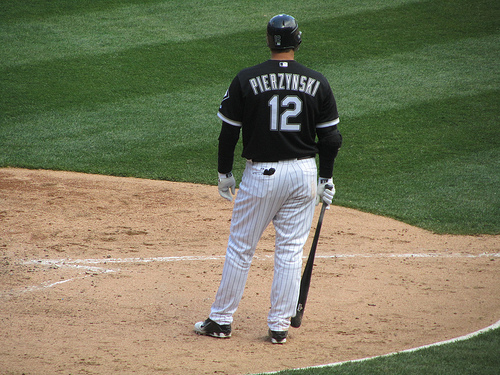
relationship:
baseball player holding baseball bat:
[189, 11, 346, 343] [273, 170, 335, 337]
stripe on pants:
[263, 182, 269, 216] [223, 158, 318, 326]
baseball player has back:
[189, 11, 346, 343] [239, 59, 326, 162]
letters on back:
[245, 67, 329, 97] [239, 59, 326, 162]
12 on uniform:
[267, 92, 304, 135] [209, 60, 342, 331]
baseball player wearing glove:
[189, 11, 346, 343] [312, 176, 334, 206]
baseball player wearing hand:
[189, 11, 346, 343] [215, 172, 239, 203]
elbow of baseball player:
[319, 130, 351, 152] [189, 11, 346, 343]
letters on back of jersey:
[247, 70, 324, 95] [212, 61, 338, 160]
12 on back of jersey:
[267, 92, 304, 135] [221, 60, 342, 152]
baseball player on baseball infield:
[213, 13, 333, 343] [254, 207, 499, 373]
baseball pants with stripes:
[207, 159, 320, 331] [209, 157, 319, 328]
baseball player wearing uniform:
[189, 11, 346, 343] [209, 60, 342, 331]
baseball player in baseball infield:
[189, 11, 346, 343] [254, 207, 499, 373]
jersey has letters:
[191, 10, 343, 345] [248, 71, 323, 102]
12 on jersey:
[241, 73, 323, 157] [212, 61, 338, 160]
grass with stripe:
[334, 12, 494, 207] [326, 36, 498, 114]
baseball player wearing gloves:
[189, 11, 346, 343] [316, 180, 338, 205]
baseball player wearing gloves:
[189, 11, 346, 343] [215, 177, 232, 200]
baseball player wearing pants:
[189, 11, 346, 343] [217, 143, 311, 337]